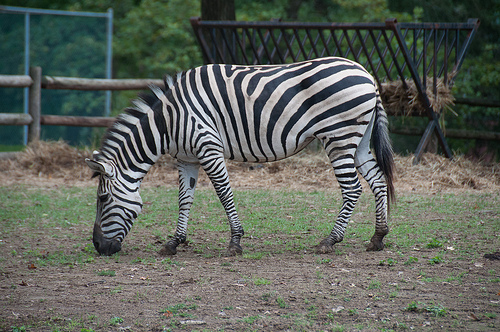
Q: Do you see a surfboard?
A: No, there are no surfboards.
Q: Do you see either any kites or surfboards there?
A: No, there are no surfboards or kites.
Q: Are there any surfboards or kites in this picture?
A: No, there are no surfboards or kites.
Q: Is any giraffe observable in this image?
A: No, there are no giraffes.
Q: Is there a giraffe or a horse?
A: No, there are no giraffes or horses.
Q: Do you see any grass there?
A: Yes, there is grass.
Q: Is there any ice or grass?
A: Yes, there is grass.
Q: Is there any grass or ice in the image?
A: Yes, there is grass.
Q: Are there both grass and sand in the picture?
A: No, there is grass but no sand.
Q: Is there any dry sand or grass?
A: Yes, there is dry grass.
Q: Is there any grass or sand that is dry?
A: Yes, the grass is dry.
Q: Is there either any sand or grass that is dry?
A: Yes, the grass is dry.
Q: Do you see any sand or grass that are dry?
A: Yes, the grass is dry.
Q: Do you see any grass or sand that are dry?
A: Yes, the grass is dry.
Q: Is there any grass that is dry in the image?
A: Yes, there is dry grass.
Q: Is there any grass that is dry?
A: Yes, there is grass that is dry.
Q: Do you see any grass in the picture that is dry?
A: Yes, there is grass that is dry.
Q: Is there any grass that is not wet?
A: Yes, there is dry grass.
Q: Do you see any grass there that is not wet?
A: Yes, there is dry grass.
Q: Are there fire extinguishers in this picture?
A: No, there are no fire extinguishers.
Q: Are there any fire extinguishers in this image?
A: No, there are no fire extinguishers.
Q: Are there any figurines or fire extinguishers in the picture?
A: No, there are no fire extinguishers or figurines.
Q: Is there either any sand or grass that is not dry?
A: No, there is grass but it is dry.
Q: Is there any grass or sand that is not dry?
A: No, there is grass but it is dry.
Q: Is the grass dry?
A: Yes, the grass is dry.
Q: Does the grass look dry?
A: Yes, the grass is dry.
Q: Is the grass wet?
A: No, the grass is dry.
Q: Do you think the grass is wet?
A: No, the grass is dry.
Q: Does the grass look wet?
A: No, the grass is dry.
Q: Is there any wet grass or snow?
A: No, there is grass but it is dry.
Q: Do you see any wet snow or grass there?
A: No, there is grass but it is dry.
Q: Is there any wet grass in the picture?
A: No, there is grass but it is dry.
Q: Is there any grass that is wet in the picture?
A: No, there is grass but it is dry.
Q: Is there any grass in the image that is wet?
A: No, there is grass but it is dry.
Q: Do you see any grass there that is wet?
A: No, there is grass but it is dry.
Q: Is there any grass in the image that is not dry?
A: No, there is grass but it is dry.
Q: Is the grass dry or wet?
A: The grass is dry.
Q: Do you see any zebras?
A: Yes, there is a zebra.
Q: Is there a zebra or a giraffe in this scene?
A: Yes, there is a zebra.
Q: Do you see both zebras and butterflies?
A: No, there is a zebra but no butterflies.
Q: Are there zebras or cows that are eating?
A: Yes, the zebra is eating.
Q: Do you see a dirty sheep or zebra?
A: Yes, there is a dirty zebra.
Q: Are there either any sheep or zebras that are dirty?
A: Yes, the zebra is dirty.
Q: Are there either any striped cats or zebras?
A: Yes, there is a striped zebra.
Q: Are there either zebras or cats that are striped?
A: Yes, the zebra is striped.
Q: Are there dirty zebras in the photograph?
A: Yes, there is a dirty zebra.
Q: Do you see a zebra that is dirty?
A: Yes, there is a zebra that is dirty.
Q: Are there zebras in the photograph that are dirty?
A: Yes, there is a zebra that is dirty.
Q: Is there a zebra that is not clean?
A: Yes, there is a dirty zebra.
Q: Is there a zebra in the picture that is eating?
A: Yes, there is a zebra that is eating.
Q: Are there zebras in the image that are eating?
A: Yes, there is a zebra that is eating.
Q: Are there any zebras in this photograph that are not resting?
A: Yes, there is a zebra that is eating.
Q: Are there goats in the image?
A: No, there are no goats.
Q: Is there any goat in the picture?
A: No, there are no goats.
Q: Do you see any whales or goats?
A: No, there are no goats or whales.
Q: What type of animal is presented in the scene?
A: The animal is a zebra.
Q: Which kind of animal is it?
A: The animal is a zebra.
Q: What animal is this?
A: That is a zebra.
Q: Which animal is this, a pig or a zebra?
A: That is a zebra.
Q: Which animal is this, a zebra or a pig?
A: That is a zebra.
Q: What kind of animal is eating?
A: The animal is a zebra.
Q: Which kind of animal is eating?
A: The animal is a zebra.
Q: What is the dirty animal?
A: The animal is a zebra.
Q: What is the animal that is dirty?
A: The animal is a zebra.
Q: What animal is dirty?
A: The animal is a zebra.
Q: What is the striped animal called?
A: The animal is a zebra.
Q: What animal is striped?
A: The animal is a zebra.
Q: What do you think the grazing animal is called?
A: The animal is a zebra.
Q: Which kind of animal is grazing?
A: The animal is a zebra.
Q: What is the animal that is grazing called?
A: The animal is a zebra.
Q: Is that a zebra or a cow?
A: That is a zebra.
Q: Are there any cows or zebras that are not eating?
A: No, there is a zebra but it is eating.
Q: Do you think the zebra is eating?
A: Yes, the zebra is eating.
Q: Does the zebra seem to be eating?
A: Yes, the zebra is eating.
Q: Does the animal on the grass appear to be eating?
A: Yes, the zebra is eating.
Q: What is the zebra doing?
A: The zebra is eating.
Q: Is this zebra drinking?
A: No, the zebra is eating.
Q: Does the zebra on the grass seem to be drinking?
A: No, the zebra is eating.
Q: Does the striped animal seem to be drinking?
A: No, the zebra is eating.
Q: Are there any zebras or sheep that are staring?
A: No, there is a zebra but it is eating.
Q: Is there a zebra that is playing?
A: No, there is a zebra but it is eating.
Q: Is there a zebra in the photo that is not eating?
A: No, there is a zebra but it is eating.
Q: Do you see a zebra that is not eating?
A: No, there is a zebra but it is eating.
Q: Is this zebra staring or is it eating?
A: The zebra is eating.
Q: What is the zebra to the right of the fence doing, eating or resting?
A: The zebra is eating.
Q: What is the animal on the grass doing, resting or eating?
A: The zebra is eating.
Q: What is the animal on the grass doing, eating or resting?
A: The zebra is eating.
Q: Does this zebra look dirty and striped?
A: Yes, the zebra is dirty and striped.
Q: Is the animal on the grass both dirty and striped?
A: Yes, the zebra is dirty and striped.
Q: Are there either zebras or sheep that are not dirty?
A: No, there is a zebra but it is dirty.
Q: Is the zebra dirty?
A: Yes, the zebra is dirty.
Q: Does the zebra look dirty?
A: Yes, the zebra is dirty.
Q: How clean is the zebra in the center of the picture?
A: The zebra is dirty.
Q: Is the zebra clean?
A: No, the zebra is dirty.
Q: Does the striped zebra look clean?
A: No, the zebra is dirty.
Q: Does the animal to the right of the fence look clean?
A: No, the zebra is dirty.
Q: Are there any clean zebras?
A: No, there is a zebra but it is dirty.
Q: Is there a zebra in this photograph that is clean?
A: No, there is a zebra but it is dirty.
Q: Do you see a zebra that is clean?
A: No, there is a zebra but it is dirty.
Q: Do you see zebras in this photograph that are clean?
A: No, there is a zebra but it is dirty.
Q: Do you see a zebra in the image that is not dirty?
A: No, there is a zebra but it is dirty.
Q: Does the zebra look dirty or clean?
A: The zebra is dirty.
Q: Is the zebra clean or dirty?
A: The zebra is dirty.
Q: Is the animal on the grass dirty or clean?
A: The zebra is dirty.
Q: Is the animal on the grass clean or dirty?
A: The zebra is dirty.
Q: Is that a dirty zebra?
A: Yes, that is a dirty zebra.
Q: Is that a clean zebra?
A: No, that is a dirty zebra.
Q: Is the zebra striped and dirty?
A: Yes, the zebra is striped and dirty.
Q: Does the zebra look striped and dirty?
A: Yes, the zebra is striped and dirty.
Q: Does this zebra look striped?
A: Yes, the zebra is striped.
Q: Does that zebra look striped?
A: Yes, the zebra is striped.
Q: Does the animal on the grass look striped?
A: Yes, the zebra is striped.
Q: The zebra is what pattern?
A: The zebra is striped.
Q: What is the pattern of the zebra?
A: The zebra is striped.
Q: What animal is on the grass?
A: The zebra is on the grass.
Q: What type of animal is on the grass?
A: The animal is a zebra.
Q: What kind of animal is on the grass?
A: The animal is a zebra.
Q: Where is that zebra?
A: The zebra is on the grass.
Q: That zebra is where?
A: The zebra is on the grass.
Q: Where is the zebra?
A: The zebra is on the grass.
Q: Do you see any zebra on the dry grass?
A: Yes, there is a zebra on the grass.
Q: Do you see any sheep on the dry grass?
A: No, there is a zebra on the grass.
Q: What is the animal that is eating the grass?
A: The animal is a zebra.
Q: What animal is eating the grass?
A: The animal is a zebra.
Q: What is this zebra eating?
A: The zebra is eating grass.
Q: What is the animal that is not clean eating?
A: The zebra is eating grass.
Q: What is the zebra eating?
A: The zebra is eating grass.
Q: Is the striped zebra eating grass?
A: Yes, the zebra is eating grass.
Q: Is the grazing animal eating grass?
A: Yes, the zebra is eating grass.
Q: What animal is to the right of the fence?
A: The animal is a zebra.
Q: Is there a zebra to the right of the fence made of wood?
A: Yes, there is a zebra to the right of the fence.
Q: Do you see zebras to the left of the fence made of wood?
A: No, the zebra is to the right of the fence.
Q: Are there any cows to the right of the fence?
A: No, there is a zebra to the right of the fence.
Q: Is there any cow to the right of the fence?
A: No, there is a zebra to the right of the fence.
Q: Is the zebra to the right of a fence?
A: Yes, the zebra is to the right of a fence.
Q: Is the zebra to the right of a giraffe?
A: No, the zebra is to the right of a fence.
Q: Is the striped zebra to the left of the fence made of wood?
A: No, the zebra is to the right of the fence.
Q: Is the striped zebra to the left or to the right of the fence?
A: The zebra is to the right of the fence.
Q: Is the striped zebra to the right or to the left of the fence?
A: The zebra is to the right of the fence.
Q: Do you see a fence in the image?
A: Yes, there is a fence.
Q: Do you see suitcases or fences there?
A: Yes, there is a fence.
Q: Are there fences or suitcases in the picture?
A: Yes, there is a fence.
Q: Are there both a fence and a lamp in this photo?
A: No, there is a fence but no lamps.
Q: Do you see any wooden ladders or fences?
A: Yes, there is a wood fence.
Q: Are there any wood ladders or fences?
A: Yes, there is a wood fence.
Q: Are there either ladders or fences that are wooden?
A: Yes, the fence is wooden.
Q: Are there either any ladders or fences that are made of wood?
A: Yes, the fence is made of wood.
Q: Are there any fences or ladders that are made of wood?
A: Yes, the fence is made of wood.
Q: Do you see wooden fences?
A: Yes, there is a wood fence.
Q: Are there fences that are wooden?
A: Yes, there is a fence that is wooden.